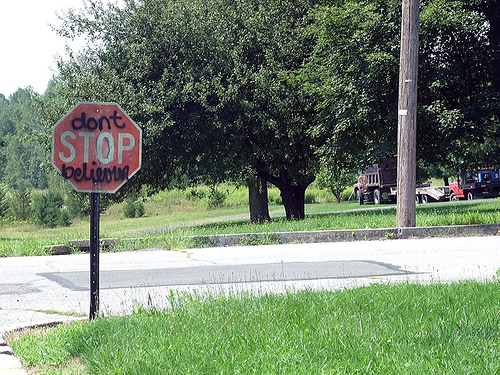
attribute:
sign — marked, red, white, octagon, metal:
[50, 102, 144, 197]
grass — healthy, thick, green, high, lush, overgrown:
[16, 285, 499, 375]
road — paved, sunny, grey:
[1, 238, 500, 323]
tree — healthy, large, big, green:
[48, 2, 499, 221]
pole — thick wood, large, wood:
[398, 0, 421, 228]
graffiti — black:
[65, 113, 132, 180]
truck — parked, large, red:
[353, 161, 399, 206]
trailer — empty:
[418, 183, 451, 203]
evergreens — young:
[6, 180, 167, 223]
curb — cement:
[59, 217, 500, 257]